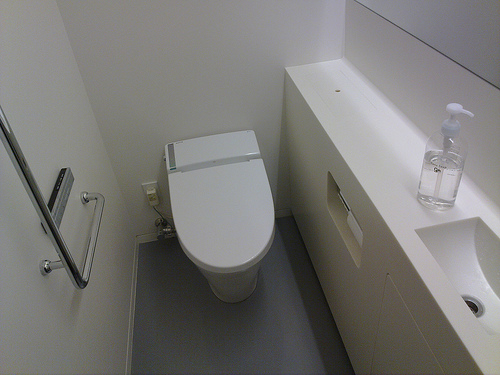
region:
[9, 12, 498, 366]
Picture is taken indoors.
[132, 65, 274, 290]
The toilet is white.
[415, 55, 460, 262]
A bottle of soap is on the counter.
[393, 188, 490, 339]
The sink is white.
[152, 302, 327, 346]
The floor is grey.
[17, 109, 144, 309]
A chrome bar is on the wall.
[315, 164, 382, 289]
Toilet rolls are on the side of the wall.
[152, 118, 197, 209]
The toilet handle is chrome.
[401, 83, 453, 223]
The soap dispenser is clear.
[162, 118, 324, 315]
The toilet seat lid is down.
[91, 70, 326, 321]
white toilet in narrow space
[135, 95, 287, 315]
lid on toilet in down position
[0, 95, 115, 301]
metal railing on a wall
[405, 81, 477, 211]
dispenser with clear liquid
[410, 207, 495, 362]
narrow and curved sink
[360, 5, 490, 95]
dark line between panels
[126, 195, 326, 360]
grey floor around toilet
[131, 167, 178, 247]
plug in outlet with dark wire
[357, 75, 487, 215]
soap on a white counter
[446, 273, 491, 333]
dark drain on bottom of sink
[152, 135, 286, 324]
toilet bowl is white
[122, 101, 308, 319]
a toilet in a rest room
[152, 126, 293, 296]
the lid on the toilet is down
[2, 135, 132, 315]
a safety bar on the wall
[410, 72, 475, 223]
hand soap/sanitizer by the sink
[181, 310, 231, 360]
the floor is grey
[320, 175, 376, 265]
a toilet paper holder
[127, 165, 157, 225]
an electric deodorizor ?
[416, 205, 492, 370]
the sink is rectangular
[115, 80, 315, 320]
the toilet is white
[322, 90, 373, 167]
the cabinet/shelf is white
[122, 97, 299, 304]
white toilet in bathroom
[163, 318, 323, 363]
gray flooring in bathroom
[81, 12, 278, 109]
gray wall in bathroom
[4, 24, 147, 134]
gray wall in bathroom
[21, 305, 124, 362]
gray wall in bathroom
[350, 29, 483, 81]
gray wall in bathroom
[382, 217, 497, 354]
white sink in bathroom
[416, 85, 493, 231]
clear bottle of hand sanitizer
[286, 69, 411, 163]
white counter in bathroom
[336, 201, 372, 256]
white tissue in bathroom